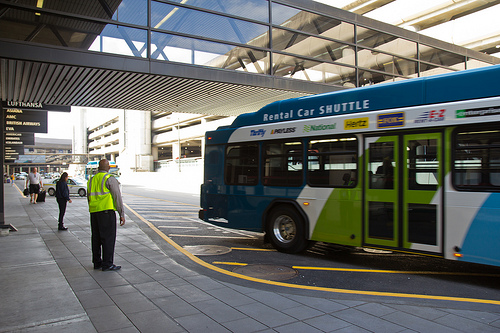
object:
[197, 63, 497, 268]
bus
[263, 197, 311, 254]
wheel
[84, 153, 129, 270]
man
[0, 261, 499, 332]
street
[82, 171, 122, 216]
vest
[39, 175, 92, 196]
car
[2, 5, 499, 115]
bridge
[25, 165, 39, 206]
man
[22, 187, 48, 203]
luggage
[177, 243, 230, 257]
cover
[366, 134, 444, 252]
door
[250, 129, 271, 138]
logo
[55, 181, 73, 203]
jacket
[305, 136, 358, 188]
window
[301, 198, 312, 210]
light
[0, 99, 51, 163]
signs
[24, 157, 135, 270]
people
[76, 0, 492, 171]
garage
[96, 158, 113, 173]
head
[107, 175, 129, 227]
arm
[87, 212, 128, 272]
legs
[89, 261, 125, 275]
shoes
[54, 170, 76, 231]
woman